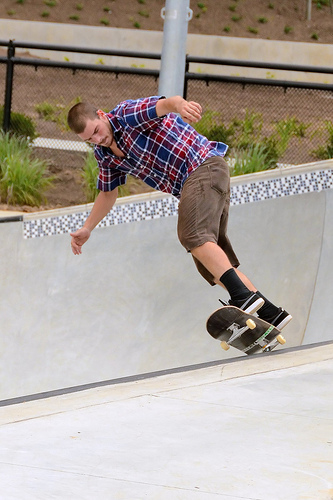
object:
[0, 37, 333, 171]
fence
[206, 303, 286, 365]
board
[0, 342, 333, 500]
ground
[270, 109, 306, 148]
bush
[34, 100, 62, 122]
bush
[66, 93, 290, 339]
man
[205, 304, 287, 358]
skateboard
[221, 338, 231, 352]
wheel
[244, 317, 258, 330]
wheel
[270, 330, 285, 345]
wheel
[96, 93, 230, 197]
shirt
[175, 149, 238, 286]
shorts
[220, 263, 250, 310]
socks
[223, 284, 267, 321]
shoes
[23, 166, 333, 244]
tile trim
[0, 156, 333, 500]
pool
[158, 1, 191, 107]
pole